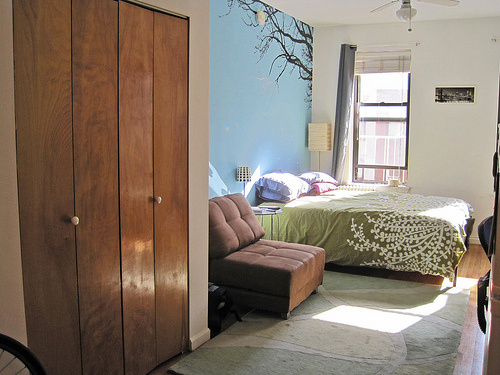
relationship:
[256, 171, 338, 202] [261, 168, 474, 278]
pillows on bed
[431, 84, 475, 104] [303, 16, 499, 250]
picture hanging on wall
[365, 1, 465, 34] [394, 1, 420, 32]
ceiling fan with a lamp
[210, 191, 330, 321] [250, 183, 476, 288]
brown chair by bed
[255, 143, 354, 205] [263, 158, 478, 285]
pillows on bed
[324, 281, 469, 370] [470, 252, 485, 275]
rug on floor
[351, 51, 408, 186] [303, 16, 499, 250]
window on wall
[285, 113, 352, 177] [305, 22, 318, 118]
lamp in corner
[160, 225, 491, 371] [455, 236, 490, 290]
ground has floor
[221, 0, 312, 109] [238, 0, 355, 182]
decal in corner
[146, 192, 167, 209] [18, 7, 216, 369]
knob on closet door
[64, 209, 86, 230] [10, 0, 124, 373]
knob on door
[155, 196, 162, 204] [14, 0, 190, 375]
knob on closet door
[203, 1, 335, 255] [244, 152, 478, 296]
wall behind bed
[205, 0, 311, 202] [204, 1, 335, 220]
decal on wall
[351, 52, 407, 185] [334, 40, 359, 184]
window has gray curtain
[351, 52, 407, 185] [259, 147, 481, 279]
window next to bed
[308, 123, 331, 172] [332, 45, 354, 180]
lamp next to curtains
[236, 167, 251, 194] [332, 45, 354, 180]
lamp next to curtains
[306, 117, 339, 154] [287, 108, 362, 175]
shade on lamp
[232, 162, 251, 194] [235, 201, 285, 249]
lamp on table